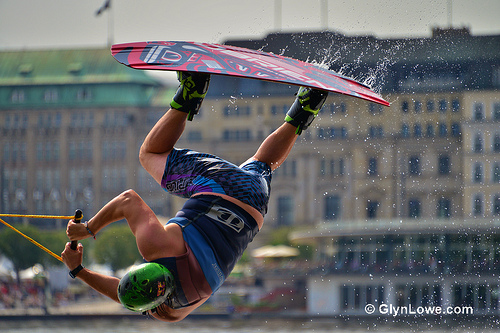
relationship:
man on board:
[60, 70, 330, 322] [109, 41, 391, 106]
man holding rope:
[72, 140, 305, 318] [6, 187, 84, 288]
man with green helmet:
[60, 70, 330, 322] [117, 262, 176, 313]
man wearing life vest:
[60, 70, 330, 322] [155, 192, 263, 312]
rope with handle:
[0, 212, 74, 261] [69, 207, 82, 277]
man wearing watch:
[60, 70, 330, 322] [65, 264, 82, 279]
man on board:
[60, 70, 330, 322] [97, 35, 407, 111]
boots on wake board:
[166, 70, 209, 122] [128, 26, 403, 117]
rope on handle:
[0, 212, 74, 261] [54, 209, 80, 261]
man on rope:
[60, 70, 330, 322] [2, 212, 84, 261]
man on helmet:
[60, 70, 330, 322] [107, 260, 182, 323]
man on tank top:
[60, 70, 330, 322] [161, 187, 260, 311]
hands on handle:
[61, 219, 88, 269] [70, 209, 83, 248]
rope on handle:
[2, 212, 84, 261] [68, 208, 82, 250]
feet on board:
[172, 73, 322, 119] [109, 41, 391, 106]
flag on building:
[92, 2, 113, 17] [2, 30, 499, 246]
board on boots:
[109, 41, 391, 106] [154, 64, 330, 137]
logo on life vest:
[205, 204, 245, 232] [143, 192, 264, 309]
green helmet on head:
[114, 260, 175, 313] [112, 260, 173, 317]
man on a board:
[60, 70, 330, 322] [109, 41, 391, 106]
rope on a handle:
[0, 212, 74, 261] [57, 210, 84, 280]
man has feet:
[60, 70, 330, 322] [181, 75, 309, 144]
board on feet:
[109, 41, 391, 106] [181, 75, 309, 144]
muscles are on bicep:
[111, 187, 178, 254] [116, 185, 162, 266]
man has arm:
[60, 70, 330, 322] [55, 184, 170, 245]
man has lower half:
[60, 70, 330, 322] [86, 14, 431, 185]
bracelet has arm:
[65, 214, 106, 238] [69, 182, 172, 256]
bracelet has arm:
[85, 221, 96, 240] [69, 182, 172, 256]